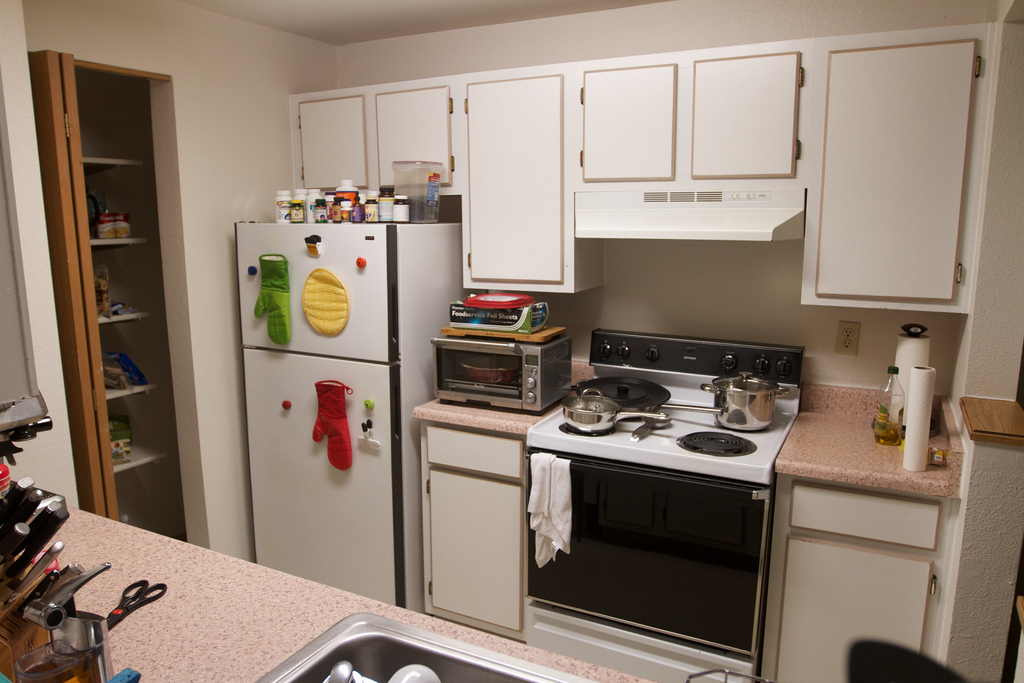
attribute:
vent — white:
[554, 164, 789, 288]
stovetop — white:
[539, 360, 783, 477]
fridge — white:
[228, 337, 429, 606]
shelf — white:
[86, 359, 169, 421]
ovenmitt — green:
[250, 246, 292, 349]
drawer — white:
[518, 598, 758, 679]